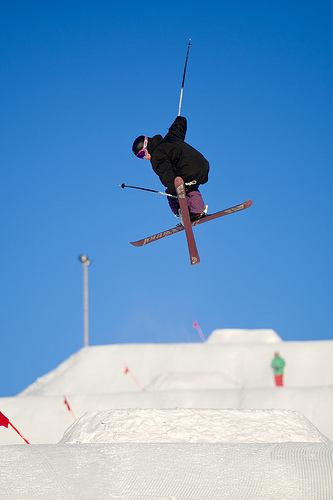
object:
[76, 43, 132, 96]
air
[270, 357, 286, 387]
clothing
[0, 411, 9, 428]
flag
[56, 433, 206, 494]
snow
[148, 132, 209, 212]
coat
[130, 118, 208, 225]
person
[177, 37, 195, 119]
pole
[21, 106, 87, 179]
air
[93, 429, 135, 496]
snow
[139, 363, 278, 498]
slopes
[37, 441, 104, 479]
snow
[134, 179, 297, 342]
jump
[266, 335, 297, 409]
snow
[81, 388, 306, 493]
ramps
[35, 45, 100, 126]
sky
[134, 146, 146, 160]
goggles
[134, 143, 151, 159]
face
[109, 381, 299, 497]
ramp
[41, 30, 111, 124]
air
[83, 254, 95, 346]
pole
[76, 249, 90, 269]
lights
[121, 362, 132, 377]
flag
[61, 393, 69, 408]
flag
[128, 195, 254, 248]
skis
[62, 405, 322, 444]
snow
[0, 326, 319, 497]
ground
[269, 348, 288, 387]
person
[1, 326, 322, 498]
snow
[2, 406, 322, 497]
steps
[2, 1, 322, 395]
sky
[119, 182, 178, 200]
stick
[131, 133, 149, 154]
helmet